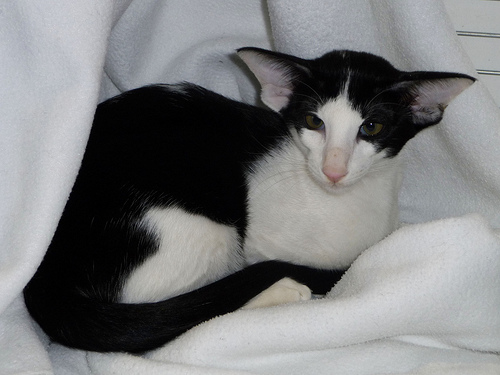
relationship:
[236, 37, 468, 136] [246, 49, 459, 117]
ears have pink insides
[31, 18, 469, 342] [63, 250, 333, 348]
cat has a tail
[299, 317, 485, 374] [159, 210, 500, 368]
wrinkle on blanket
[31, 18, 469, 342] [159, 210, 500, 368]
cat on blanket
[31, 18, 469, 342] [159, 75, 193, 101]
cat has a spot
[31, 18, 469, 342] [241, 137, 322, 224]
cat has whiskers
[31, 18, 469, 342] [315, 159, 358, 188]
cat has a nose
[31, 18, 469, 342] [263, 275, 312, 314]
cat has a foot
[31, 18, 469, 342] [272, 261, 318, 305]
cat has a toe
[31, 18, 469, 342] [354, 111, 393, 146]
cat has an eye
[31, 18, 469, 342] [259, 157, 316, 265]
cat has fur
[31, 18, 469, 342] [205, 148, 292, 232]
cat colored black & white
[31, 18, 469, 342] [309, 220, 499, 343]
cat lying on a towel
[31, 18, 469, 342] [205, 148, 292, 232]
cat colored both black & white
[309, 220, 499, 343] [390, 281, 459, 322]
towel colored white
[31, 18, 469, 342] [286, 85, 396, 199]
cat has a face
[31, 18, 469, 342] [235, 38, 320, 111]
cat has an ear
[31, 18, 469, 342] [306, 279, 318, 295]
cat has a nail